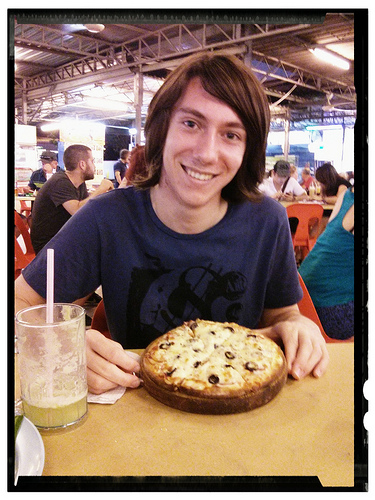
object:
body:
[11, 173, 331, 397]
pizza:
[137, 317, 288, 415]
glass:
[16, 304, 89, 435]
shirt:
[19, 178, 306, 350]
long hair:
[124, 52, 270, 197]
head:
[125, 52, 271, 204]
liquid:
[22, 391, 88, 429]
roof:
[12, 14, 357, 132]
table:
[24, 331, 354, 486]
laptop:
[15, 469, 349, 491]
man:
[5, 51, 333, 395]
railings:
[13, 20, 110, 63]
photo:
[13, 14, 353, 489]